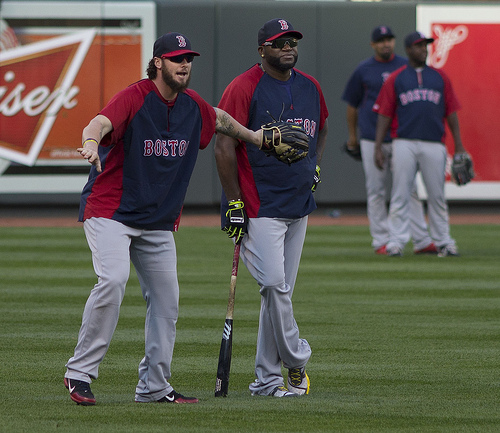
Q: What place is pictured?
A: It is a field.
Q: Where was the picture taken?
A: It was taken at the field.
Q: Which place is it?
A: It is a field.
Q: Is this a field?
A: Yes, it is a field.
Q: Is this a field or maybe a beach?
A: It is a field.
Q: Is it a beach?
A: No, it is a field.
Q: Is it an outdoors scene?
A: Yes, it is outdoors.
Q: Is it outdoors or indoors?
A: It is outdoors.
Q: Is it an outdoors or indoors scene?
A: It is outdoors.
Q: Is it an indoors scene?
A: No, it is outdoors.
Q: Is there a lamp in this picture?
A: No, there are no lamps.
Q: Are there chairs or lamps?
A: No, there are no lamps or chairs.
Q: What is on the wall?
A: The sign is on the wall.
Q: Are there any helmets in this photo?
A: No, there are no helmets.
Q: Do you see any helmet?
A: No, there are no helmets.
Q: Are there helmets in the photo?
A: No, there are no helmets.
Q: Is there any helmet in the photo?
A: No, there are no helmets.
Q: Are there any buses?
A: No, there are no buses.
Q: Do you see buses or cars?
A: No, there are no buses or cars.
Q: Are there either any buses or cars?
A: No, there are no buses or cars.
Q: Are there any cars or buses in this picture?
A: No, there are no buses or cars.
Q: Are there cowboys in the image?
A: No, there are no cowboys.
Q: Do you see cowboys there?
A: No, there are no cowboys.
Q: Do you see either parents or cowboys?
A: No, there are no cowboys or parents.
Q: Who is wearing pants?
A: The man is wearing pants.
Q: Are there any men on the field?
A: Yes, there is a man on the field.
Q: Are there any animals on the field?
A: No, there is a man on the field.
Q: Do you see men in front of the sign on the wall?
A: Yes, there is a man in front of the sign.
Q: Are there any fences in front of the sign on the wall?
A: No, there is a man in front of the sign.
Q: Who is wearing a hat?
A: The man is wearing a hat.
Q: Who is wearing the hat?
A: The man is wearing a hat.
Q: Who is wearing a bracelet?
A: The man is wearing a bracelet.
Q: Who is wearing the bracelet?
A: The man is wearing a bracelet.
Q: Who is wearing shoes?
A: The man is wearing shoes.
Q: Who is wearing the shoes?
A: The man is wearing shoes.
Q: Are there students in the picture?
A: No, there are no students.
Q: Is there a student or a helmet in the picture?
A: No, there are no students or helmets.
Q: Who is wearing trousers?
A: The man is wearing trousers.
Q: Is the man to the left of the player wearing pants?
A: Yes, the man is wearing pants.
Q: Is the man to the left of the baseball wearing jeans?
A: No, the man is wearing pants.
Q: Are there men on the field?
A: Yes, there is a man on the field.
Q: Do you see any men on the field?
A: Yes, there is a man on the field.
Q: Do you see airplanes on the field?
A: No, there is a man on the field.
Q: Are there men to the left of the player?
A: Yes, there is a man to the left of the player.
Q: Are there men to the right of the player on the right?
A: No, the man is to the left of the player.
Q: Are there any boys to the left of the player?
A: No, there is a man to the left of the player.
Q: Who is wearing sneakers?
A: The man is wearing sneakers.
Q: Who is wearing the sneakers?
A: The man is wearing sneakers.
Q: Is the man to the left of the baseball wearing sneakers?
A: Yes, the man is wearing sneakers.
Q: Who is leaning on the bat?
A: The man is leaning on the bat.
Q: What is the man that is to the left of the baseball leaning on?
A: The man is leaning on the bat.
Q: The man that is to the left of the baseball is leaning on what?
A: The man is leaning on the bat.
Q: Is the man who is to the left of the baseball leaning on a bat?
A: Yes, the man is leaning on a bat.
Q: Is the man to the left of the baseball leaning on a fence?
A: No, the man is leaning on a bat.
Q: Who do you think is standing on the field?
A: The man is standing on the field.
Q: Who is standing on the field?
A: The man is standing on the field.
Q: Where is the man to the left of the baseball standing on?
A: The man is standing on the field.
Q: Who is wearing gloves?
A: The man is wearing gloves.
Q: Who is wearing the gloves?
A: The man is wearing gloves.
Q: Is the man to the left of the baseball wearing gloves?
A: Yes, the man is wearing gloves.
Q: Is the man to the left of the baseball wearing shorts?
A: No, the man is wearing gloves.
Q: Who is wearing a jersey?
A: The man is wearing a jersey.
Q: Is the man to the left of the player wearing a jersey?
A: Yes, the man is wearing a jersey.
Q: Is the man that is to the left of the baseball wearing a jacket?
A: No, the man is wearing a jersey.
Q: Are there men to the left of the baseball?
A: Yes, there is a man to the left of the baseball.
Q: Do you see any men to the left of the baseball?
A: Yes, there is a man to the left of the baseball.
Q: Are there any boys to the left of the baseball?
A: No, there is a man to the left of the baseball.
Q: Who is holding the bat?
A: The man is holding the bat.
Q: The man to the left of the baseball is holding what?
A: The man is holding the bat.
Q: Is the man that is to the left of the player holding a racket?
A: No, the man is holding the bat.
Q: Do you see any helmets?
A: No, there are no helmets.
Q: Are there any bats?
A: Yes, there is a bat.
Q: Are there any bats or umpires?
A: Yes, there is a bat.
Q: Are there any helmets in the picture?
A: No, there are no helmets.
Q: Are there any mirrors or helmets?
A: No, there are no helmets or mirrors.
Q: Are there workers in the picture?
A: No, there are no workers.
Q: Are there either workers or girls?
A: No, there are no workers or girls.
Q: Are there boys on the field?
A: No, there is a man on the field.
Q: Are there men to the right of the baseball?
A: Yes, there is a man to the right of the baseball.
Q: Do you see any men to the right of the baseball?
A: Yes, there is a man to the right of the baseball.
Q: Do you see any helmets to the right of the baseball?
A: No, there is a man to the right of the baseball.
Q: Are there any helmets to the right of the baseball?
A: No, there is a man to the right of the baseball.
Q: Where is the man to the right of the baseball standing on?
A: The man is standing on the field.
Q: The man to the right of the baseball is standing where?
A: The man is standing on the field.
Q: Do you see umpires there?
A: No, there are no umpires.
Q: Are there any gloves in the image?
A: Yes, there are gloves.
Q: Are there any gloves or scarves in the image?
A: Yes, there are gloves.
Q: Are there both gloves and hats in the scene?
A: Yes, there are both gloves and a hat.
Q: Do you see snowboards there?
A: No, there are no snowboards.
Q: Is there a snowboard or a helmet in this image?
A: No, there are no snowboards or helmets.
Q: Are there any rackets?
A: No, there are no rackets.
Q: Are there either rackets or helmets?
A: No, there are no rackets or helmets.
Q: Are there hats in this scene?
A: Yes, there is a hat.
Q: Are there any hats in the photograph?
A: Yes, there is a hat.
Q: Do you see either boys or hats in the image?
A: Yes, there is a hat.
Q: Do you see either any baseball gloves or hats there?
A: Yes, there is a baseball hat.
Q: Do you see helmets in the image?
A: No, there are no helmets.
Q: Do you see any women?
A: No, there are no women.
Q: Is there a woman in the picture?
A: No, there are no women.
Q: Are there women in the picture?
A: No, there are no women.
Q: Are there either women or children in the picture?
A: No, there are no women or children.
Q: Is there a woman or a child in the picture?
A: No, there are no women or children.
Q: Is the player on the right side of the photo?
A: Yes, the player is on the right of the image.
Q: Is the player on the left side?
A: No, the player is on the right of the image.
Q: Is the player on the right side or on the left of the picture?
A: The player is on the right of the image.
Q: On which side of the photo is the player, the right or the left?
A: The player is on the right of the image.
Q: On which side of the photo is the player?
A: The player is on the right of the image.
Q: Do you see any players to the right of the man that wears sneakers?
A: Yes, there is a player to the right of the man.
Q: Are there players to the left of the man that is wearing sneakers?
A: No, the player is to the right of the man.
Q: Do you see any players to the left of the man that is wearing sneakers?
A: No, the player is to the right of the man.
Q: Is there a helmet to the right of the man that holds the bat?
A: No, there is a player to the right of the man.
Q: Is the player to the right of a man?
A: Yes, the player is to the right of a man.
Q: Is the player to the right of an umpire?
A: No, the player is to the right of a man.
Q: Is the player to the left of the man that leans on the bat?
A: No, the player is to the right of the man.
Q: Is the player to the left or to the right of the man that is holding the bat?
A: The player is to the right of the man.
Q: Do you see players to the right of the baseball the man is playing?
A: Yes, there is a player to the right of the baseball.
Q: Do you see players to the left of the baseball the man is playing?
A: No, the player is to the right of the baseball.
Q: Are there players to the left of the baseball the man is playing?
A: No, the player is to the right of the baseball.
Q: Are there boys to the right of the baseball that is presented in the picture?
A: No, there is a player to the right of the baseball.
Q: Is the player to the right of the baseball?
A: Yes, the player is to the right of the baseball.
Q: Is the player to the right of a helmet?
A: No, the player is to the right of the baseball.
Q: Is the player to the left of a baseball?
A: No, the player is to the right of a baseball.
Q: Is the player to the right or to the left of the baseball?
A: The player is to the right of the baseball.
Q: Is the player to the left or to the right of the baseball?
A: The player is to the right of the baseball.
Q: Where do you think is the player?
A: The player is on the field.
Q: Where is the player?
A: The player is on the field.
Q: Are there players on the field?
A: Yes, there is a player on the field.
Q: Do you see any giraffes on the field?
A: No, there is a player on the field.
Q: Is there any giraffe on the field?
A: No, there is a player on the field.